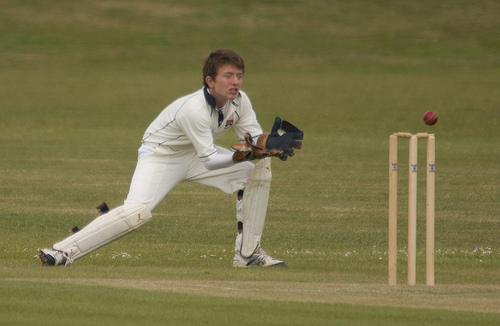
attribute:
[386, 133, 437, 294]
cricket — wooden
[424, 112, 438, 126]
ball — flying, red, small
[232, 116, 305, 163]
gloves — black, brown, blue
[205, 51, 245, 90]
hair — brown, short, dark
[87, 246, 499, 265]
flowers — small, white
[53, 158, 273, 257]
shin gaurds — white, long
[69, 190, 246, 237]
straps — vlecro, blue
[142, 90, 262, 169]
shirt — white, blue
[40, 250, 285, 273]
cleats — white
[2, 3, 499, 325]
field — grassy, green, large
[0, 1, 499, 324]
grass — green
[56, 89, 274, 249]
uniform — white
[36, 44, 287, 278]
man — athletic, young